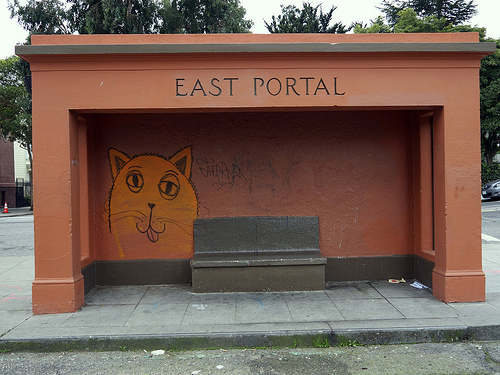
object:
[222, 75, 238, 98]
letter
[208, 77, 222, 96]
letter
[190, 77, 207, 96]
letter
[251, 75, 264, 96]
letter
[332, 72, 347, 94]
letter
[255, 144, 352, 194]
graffiti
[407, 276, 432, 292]
trash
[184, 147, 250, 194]
graffiti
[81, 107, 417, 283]
back wall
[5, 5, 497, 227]
background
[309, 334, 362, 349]
weeds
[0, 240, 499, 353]
sidewalk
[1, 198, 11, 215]
cone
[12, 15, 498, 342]
stop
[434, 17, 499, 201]
trees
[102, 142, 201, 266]
cat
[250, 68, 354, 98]
portal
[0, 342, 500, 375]
road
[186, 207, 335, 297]
bench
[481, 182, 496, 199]
nose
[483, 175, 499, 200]
car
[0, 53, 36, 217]
tree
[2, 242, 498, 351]
floor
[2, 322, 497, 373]
street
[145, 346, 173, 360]
trash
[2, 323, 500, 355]
curb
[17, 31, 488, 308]
bus stop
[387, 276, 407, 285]
litter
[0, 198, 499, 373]
ground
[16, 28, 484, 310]
portal